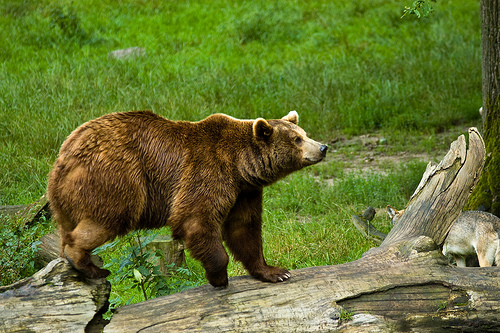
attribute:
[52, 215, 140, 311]
leg — back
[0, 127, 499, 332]
tree — fallen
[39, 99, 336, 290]
bear — brown, furry